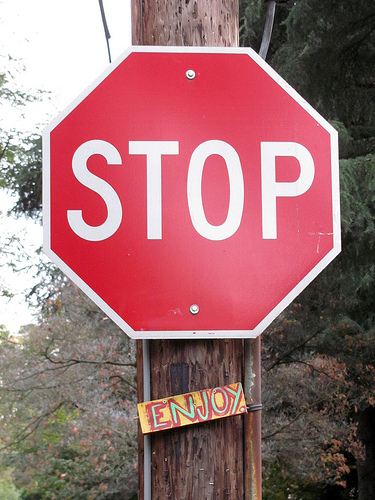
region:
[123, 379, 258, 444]
a small hand-made signe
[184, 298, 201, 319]
a double headed nail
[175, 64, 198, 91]
a double headed nail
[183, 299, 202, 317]
nail used to fasten sign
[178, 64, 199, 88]
nail used to fasten sign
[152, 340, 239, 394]
wooden pole for mounting sign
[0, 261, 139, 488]
fruit tree that is blossoming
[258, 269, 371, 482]
blossoming fruit tree behind post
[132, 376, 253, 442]
the word "enjoy" on a sign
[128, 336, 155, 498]
a cable on the pole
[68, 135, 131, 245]
The letter S on the stop sign.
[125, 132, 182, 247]
The letter T on the stop sign.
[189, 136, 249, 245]
The letter O on the stop sign.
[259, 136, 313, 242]
The letter P on the stop sign.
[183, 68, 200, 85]
The top screw on the stop sign.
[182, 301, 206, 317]
The bottom screw on the stop sign.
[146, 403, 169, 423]
The letter E on the sign below the stop sign.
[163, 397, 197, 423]
The letter N on the sign below the stop sign.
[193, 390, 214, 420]
The letter J on the sign below the stop sign.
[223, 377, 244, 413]
The letter Y on the sign below the stop sign.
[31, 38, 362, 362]
the red and white stop sign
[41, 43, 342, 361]
the stop sign on a pole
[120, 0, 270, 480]
the pole is brown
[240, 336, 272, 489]
the pipe under the stop sign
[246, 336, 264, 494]
the pipe is rusty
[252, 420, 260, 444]
the rust on the pipe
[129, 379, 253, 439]
enjoy sign under stop sign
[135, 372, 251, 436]
enjoy sign is yellow, red, and blue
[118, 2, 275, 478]
pole is made of wood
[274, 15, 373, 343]
tree with green leaves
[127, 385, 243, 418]
Sign that says "Enjoy"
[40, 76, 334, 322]
Red stop sign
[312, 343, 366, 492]
Decaying leaves in background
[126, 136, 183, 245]
T on stop sign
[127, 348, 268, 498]
Telephone pole is brown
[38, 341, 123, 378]
Branch of tree in background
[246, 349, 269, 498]
Rusty metal pole on telephone pole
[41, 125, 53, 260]
White border of sign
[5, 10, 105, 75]
Sky is white and bright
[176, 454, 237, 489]
Small clips in pole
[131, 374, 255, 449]
small wooden sign on telephone pole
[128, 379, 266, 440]
enjoy sign on pole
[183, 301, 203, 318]
bolt holding stop sign on pole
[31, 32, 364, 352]
stop sign bolted to pole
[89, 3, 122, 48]
power line connected to pole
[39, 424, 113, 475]
pink blossoms in the tree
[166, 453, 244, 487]
staples stuck in the telephone pole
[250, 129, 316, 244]
letter pee on a red background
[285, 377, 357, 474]
trees with blossoms and leaves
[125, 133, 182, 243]
white tee on a red background